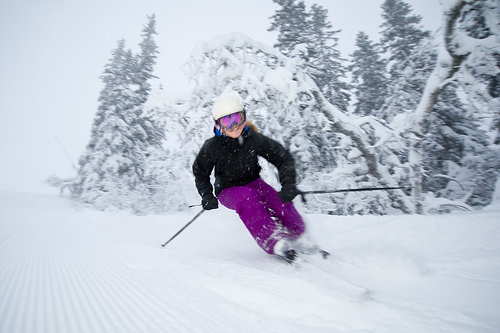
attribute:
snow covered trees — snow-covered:
[85, 6, 497, 210]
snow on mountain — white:
[4, 222, 497, 332]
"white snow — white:
[1, 186, 499, 326]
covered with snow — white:
[48, 0, 495, 239]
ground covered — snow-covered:
[8, 175, 498, 327]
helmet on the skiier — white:
[199, 89, 262, 121]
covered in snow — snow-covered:
[74, 0, 494, 230]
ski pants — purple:
[208, 180, 331, 268]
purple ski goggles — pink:
[216, 111, 250, 140]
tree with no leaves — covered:
[158, 30, 422, 228]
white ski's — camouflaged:
[160, 179, 399, 314]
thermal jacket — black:
[165, 122, 305, 205]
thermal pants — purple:
[205, 173, 320, 257]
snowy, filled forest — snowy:
[64, 0, 497, 225]